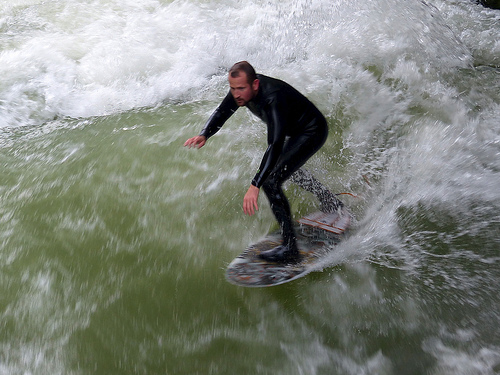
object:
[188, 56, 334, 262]
man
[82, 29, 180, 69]
wave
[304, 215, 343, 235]
patterned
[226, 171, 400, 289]
surfboard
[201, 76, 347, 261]
shiny wetsuit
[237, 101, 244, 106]
goatee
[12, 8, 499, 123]
crashing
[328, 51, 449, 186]
wave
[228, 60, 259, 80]
short hair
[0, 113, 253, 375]
green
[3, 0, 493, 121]
water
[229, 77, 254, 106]
concentrating face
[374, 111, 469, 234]
splashing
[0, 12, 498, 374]
ocean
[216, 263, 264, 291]
tip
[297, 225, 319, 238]
logo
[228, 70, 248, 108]
facial expression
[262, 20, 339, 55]
waves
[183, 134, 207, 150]
right hand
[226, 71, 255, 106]
surfers face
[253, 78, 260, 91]
left ear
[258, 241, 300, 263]
shoes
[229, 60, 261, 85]
hair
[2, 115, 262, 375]
calm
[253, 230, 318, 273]
design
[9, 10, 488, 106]
appears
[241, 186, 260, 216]
hand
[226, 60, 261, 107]
head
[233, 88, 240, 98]
nose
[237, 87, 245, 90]
eye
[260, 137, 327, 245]
leg